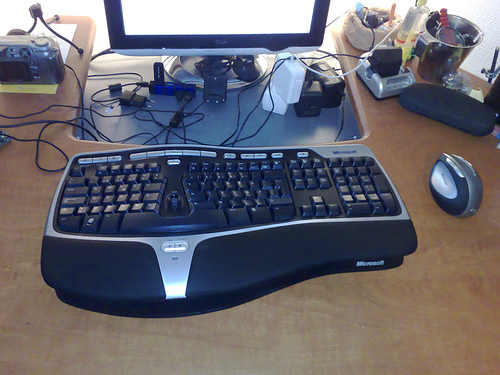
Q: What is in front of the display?
A: Keyboard.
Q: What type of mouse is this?
A: Optical mouse.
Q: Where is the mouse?
A: On the table.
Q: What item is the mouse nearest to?
A: The keyboard.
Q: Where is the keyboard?
A: On the desk.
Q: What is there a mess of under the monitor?
A: Cables and power cords.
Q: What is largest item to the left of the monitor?
A: A digital camera.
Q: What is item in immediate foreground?
A: Keyboard.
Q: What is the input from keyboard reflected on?
A: Monitor.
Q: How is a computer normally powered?
A: Electricity.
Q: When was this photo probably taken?
A: Daytime.